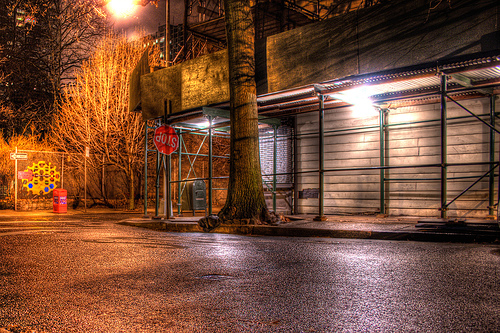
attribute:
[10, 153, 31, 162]
sign — white 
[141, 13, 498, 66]
scaffolding — green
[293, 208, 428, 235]
sidewalk — lit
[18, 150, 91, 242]
gate — Yellow , blue 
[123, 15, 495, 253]
building — old, abandoned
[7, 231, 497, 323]
road — asphalt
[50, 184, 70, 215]
trash can — pink 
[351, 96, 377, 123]
light — on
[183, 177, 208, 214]
can — green 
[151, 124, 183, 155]
sign — upside down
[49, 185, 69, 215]
cone — orange, white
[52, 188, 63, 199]
box — red 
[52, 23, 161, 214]
tree — bare